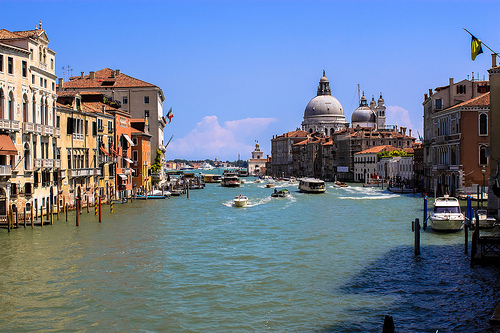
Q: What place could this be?
A: It is a river.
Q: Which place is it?
A: It is a river.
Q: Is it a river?
A: Yes, it is a river.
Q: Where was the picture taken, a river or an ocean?
A: It was taken at a river.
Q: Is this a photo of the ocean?
A: No, the picture is showing the river.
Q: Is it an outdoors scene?
A: Yes, it is outdoors.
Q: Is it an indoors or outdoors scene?
A: It is outdoors.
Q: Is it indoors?
A: No, it is outdoors.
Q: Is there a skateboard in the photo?
A: No, there are no skateboards.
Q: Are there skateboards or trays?
A: No, there are no skateboards or trays.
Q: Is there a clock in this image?
A: No, there are no clocks.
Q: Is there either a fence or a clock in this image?
A: No, there are no clocks or fences.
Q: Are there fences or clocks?
A: No, there are no clocks or fences.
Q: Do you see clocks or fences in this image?
A: No, there are no clocks or fences.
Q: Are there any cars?
A: No, there are no cars.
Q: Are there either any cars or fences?
A: No, there are no cars or fences.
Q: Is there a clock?
A: No, there are no clocks.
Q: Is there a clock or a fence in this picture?
A: No, there are no clocks or fences.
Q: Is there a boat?
A: Yes, there is a boat.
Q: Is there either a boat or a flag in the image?
A: Yes, there is a boat.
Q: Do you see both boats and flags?
A: Yes, there are both a boat and a flag.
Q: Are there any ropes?
A: No, there are no ropes.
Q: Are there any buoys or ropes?
A: No, there are no ropes or buoys.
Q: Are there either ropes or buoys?
A: No, there are no ropes or buoys.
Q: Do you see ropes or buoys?
A: No, there are no ropes or buoys.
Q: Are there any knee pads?
A: No, there are no knee pads.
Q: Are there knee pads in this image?
A: No, there are no knee pads.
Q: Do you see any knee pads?
A: No, there are no knee pads.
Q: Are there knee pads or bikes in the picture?
A: No, there are no knee pads or bikes.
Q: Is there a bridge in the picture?
A: No, there are no bridges.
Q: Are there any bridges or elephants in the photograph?
A: No, there are no bridges or elephants.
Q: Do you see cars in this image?
A: No, there are no cars.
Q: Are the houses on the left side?
A: Yes, the houses are on the left of the image.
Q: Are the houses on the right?
A: No, the houses are on the left of the image.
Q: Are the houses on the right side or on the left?
A: The houses are on the left of the image.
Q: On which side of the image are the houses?
A: The houses are on the left of the image.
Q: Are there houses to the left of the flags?
A: Yes, there are houses to the left of the flags.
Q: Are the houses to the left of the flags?
A: Yes, the houses are to the left of the flags.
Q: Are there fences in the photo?
A: No, there are no fences.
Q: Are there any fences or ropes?
A: No, there are no fences or ropes.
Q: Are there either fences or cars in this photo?
A: No, there are no cars or fences.